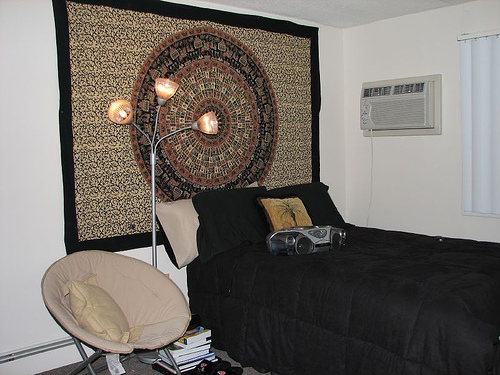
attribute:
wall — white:
[341, 1, 499, 246]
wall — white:
[1, 2, 342, 363]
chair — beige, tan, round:
[42, 246, 194, 374]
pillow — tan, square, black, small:
[256, 194, 314, 232]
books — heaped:
[150, 323, 222, 374]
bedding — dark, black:
[188, 178, 499, 373]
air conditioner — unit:
[357, 72, 442, 140]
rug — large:
[50, 0, 321, 255]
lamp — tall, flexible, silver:
[104, 73, 219, 361]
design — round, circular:
[125, 24, 280, 203]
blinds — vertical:
[455, 28, 497, 215]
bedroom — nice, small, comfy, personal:
[1, 1, 499, 374]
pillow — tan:
[62, 274, 134, 344]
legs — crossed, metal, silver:
[65, 330, 181, 374]